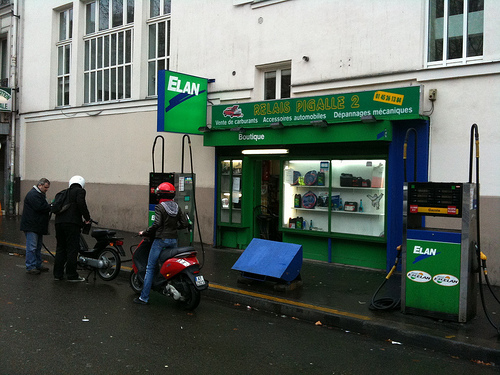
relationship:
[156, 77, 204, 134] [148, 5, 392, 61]
sign attached to building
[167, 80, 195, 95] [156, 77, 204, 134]
lettering on top of sign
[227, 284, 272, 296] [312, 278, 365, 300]
line on top of sidewalk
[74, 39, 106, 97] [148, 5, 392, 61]
window attached to building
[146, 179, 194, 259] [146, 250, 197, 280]
person on motorcycle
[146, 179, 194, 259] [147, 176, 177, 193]
person wearing helmet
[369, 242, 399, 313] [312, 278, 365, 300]
pump on sidewalk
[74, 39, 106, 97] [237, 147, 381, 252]
window for shop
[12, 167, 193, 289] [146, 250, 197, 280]
men filling motorcycle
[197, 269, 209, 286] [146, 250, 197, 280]
plate attached to motorcycle